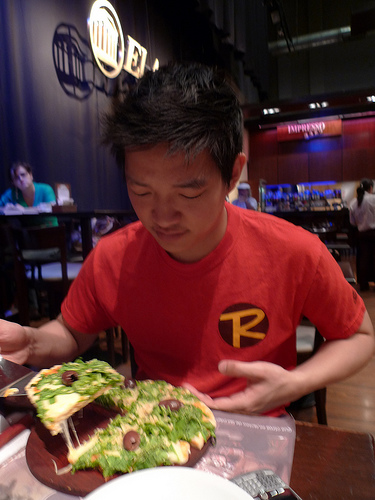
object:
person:
[0, 54, 375, 418]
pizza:
[23, 354, 214, 472]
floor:
[334, 395, 364, 417]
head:
[103, 83, 250, 249]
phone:
[241, 472, 293, 500]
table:
[283, 442, 350, 492]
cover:
[246, 422, 274, 455]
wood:
[283, 457, 315, 497]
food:
[38, 359, 97, 424]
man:
[0, 49, 375, 415]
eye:
[127, 186, 155, 203]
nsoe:
[154, 196, 173, 221]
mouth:
[149, 221, 195, 247]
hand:
[0, 316, 39, 367]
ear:
[222, 154, 251, 196]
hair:
[103, 43, 247, 180]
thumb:
[217, 350, 258, 379]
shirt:
[59, 210, 370, 425]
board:
[30, 440, 60, 479]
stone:
[59, 358, 82, 384]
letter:
[83, 16, 124, 65]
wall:
[34, 63, 100, 181]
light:
[267, 21, 351, 56]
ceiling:
[256, 52, 310, 144]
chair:
[7, 212, 99, 315]